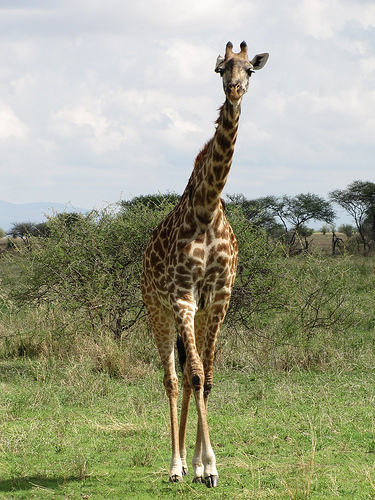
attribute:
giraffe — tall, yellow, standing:
[133, 41, 307, 416]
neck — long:
[125, 108, 270, 214]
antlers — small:
[210, 40, 255, 57]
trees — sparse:
[28, 232, 137, 322]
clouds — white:
[5, 4, 156, 124]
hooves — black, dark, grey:
[155, 455, 219, 492]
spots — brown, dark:
[138, 260, 230, 284]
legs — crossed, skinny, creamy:
[126, 301, 229, 451]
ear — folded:
[251, 51, 274, 80]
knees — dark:
[172, 369, 217, 391]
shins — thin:
[164, 433, 191, 456]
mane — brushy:
[176, 149, 223, 167]